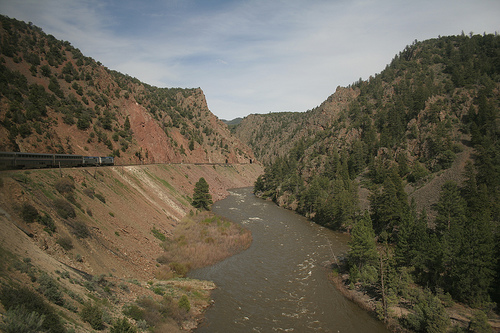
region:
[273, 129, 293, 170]
part of a valley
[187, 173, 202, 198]
edge of a valley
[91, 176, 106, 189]
side of a valley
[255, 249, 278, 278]
part of a river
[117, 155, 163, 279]
edge of a river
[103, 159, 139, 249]
part of a slope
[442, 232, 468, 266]
part of a forest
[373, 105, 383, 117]
edge of a forest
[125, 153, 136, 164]
part of the rail way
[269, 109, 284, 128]
part of the hill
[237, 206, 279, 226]
small waves on the water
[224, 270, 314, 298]
gray water in the canyon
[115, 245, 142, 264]
white spot on the bank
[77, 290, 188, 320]
green shrubbery on side of banking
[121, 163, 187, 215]
clear spot on the side of mountain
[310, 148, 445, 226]
trees dotting the mountain side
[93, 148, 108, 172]
white paint on the train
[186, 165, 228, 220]
single green tree on the bank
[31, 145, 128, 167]
long train on tracks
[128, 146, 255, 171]
train tracks cutting through the mountain side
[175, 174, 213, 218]
evergreen tree along river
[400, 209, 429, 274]
evergreen tree along river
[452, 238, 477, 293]
evergreen tree along river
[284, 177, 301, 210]
evergreen tree along river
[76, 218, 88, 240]
evergreen tree along river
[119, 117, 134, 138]
evergreen tree along river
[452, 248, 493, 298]
evergreen tree along river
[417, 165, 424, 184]
evergreen tree along river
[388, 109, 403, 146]
evergreen tree along river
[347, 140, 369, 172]
evergreen tree along river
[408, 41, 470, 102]
green trees in brown dirt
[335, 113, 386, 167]
green trees in brown dirt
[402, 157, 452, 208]
green trees in brown dirt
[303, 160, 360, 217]
green trees in brown dirt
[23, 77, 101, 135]
green trees in brown dirt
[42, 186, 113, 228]
green trees in brown dirt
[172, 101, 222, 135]
green trees in brown dirt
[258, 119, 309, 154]
green trees in brown dirt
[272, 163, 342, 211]
green trees in brown dirt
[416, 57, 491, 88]
green trees in brown dirt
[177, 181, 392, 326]
river running through a canyon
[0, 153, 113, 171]
train on the side of a canyon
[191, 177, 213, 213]
pine tree by the river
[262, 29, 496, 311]
right side of the canyon with pine trees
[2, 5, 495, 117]
high altitude clouds in the sky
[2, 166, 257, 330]
sloped area of the canyon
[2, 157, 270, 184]
railroad next to the canyon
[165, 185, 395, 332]
murky water running through a canyon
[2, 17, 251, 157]
shrubs growing on the side of a hill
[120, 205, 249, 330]
flat bank next to the river